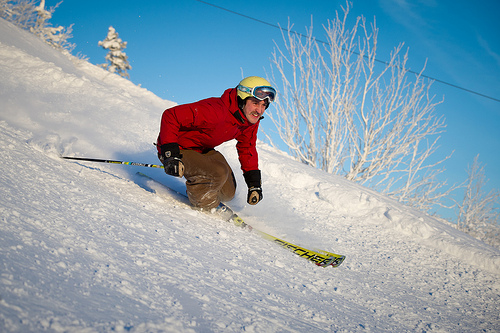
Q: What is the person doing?
A: Skiing.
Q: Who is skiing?
A: A man.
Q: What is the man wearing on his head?
A: Helmet.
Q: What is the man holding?
A: Ski poles.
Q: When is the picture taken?
A: Daytime.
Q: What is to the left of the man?
A: Shrubs.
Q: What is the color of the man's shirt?
A: Red.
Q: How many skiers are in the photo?
A: One.